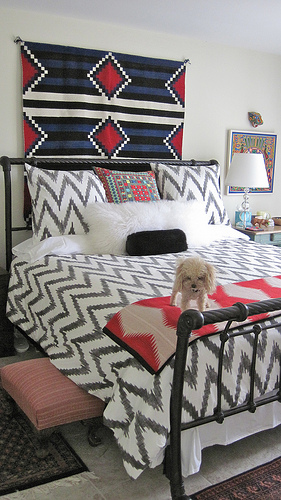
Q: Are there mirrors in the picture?
A: No, there are no mirrors.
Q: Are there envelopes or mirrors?
A: No, there are no mirrors or envelopes.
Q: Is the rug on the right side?
A: Yes, the rug is on the right of the image.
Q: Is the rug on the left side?
A: No, the rug is on the right of the image.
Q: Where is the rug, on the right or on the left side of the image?
A: The rug is on the right of the image.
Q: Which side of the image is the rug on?
A: The rug is on the right of the image.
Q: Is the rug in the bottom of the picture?
A: Yes, the rug is in the bottom of the image.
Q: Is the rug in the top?
A: No, the rug is in the bottom of the image.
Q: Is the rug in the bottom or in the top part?
A: The rug is in the bottom of the image.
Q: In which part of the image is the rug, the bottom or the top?
A: The rug is in the bottom of the image.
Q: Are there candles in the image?
A: No, there are no candles.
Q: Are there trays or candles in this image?
A: No, there are no candles or trays.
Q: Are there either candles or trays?
A: No, there are no candles or trays.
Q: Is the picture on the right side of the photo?
A: Yes, the picture is on the right of the image.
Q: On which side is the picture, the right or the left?
A: The picture is on the right of the image.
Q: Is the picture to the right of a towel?
A: No, the picture is to the right of a pillow.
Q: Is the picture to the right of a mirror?
A: No, the picture is to the right of the pillow.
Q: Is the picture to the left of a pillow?
A: No, the picture is to the right of a pillow.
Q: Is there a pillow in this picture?
A: Yes, there is a pillow.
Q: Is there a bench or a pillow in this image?
A: Yes, there is a pillow.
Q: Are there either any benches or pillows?
A: Yes, there is a pillow.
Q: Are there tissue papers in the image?
A: No, there are no tissue papers.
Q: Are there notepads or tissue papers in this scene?
A: No, there are no tissue papers or notepads.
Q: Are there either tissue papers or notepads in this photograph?
A: No, there are no tissue papers or notepads.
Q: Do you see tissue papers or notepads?
A: No, there are no tissue papers or notepads.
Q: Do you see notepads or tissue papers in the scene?
A: No, there are no tissue papers or notepads.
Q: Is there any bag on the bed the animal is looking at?
A: No, there is a pillow on the bed.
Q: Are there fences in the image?
A: No, there are no fences.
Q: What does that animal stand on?
A: The animal stands on the blanket.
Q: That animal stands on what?
A: The animal stands on the blanket.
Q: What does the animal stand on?
A: The animal stands on the blanket.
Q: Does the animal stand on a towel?
A: No, the animal stands on the blanket.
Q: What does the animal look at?
A: The animal looks at the bed.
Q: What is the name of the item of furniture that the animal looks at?
A: The piece of furniture is a bed.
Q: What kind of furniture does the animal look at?
A: The animal looks at the bed.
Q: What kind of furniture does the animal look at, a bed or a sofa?
A: The animal looks at a bed.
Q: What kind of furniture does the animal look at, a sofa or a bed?
A: The animal looks at a bed.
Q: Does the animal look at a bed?
A: Yes, the animal looks at a bed.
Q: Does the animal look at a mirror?
A: No, the animal looks at a bed.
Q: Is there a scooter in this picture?
A: No, there are no scooters.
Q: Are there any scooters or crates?
A: No, there are no scooters or crates.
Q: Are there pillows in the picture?
A: Yes, there is a pillow.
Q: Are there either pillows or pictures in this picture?
A: Yes, there is a pillow.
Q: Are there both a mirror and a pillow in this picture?
A: No, there is a pillow but no mirrors.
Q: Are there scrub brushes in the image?
A: No, there are no scrub brushes.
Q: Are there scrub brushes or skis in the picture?
A: No, there are no scrub brushes or skis.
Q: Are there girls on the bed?
A: No, there is a pillow on the bed.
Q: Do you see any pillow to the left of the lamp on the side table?
A: Yes, there is a pillow to the left of the lamp.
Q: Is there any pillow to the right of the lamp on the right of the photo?
A: No, the pillow is to the left of the lamp.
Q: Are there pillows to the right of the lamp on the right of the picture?
A: No, the pillow is to the left of the lamp.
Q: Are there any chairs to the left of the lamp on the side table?
A: No, there is a pillow to the left of the lamp.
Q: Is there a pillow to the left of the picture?
A: Yes, there is a pillow to the left of the picture.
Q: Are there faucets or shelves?
A: No, there are no faucets or shelves.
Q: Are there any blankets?
A: Yes, there is a blanket.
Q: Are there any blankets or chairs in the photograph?
A: Yes, there is a blanket.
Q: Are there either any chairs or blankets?
A: Yes, there is a blanket.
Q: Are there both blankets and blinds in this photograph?
A: No, there is a blanket but no blinds.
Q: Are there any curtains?
A: No, there are no curtains.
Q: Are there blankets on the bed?
A: Yes, there is a blanket on the bed.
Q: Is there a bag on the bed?
A: No, there is a blanket on the bed.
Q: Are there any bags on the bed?
A: No, there is a blanket on the bed.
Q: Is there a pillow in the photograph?
A: Yes, there is a pillow.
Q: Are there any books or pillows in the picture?
A: Yes, there is a pillow.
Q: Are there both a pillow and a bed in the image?
A: Yes, there are both a pillow and a bed.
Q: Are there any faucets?
A: No, there are no faucets.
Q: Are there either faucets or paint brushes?
A: No, there are no faucets or paint brushes.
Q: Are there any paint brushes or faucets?
A: No, there are no faucets or paint brushes.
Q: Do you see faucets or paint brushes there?
A: No, there are no faucets or paint brushes.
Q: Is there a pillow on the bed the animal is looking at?
A: Yes, there is a pillow on the bed.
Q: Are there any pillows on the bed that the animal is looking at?
A: Yes, there is a pillow on the bed.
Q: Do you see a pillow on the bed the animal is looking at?
A: Yes, there is a pillow on the bed.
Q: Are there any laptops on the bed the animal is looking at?
A: No, there is a pillow on the bed.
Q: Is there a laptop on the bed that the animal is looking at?
A: No, there is a pillow on the bed.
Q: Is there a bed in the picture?
A: Yes, there is a bed.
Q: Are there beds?
A: Yes, there is a bed.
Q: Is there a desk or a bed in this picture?
A: Yes, there is a bed.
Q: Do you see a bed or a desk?
A: Yes, there is a bed.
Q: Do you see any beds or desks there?
A: Yes, there is a bed.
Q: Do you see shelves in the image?
A: No, there are no shelves.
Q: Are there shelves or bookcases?
A: No, there are no shelves or bookcases.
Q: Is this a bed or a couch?
A: This is a bed.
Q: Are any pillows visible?
A: Yes, there is a pillow.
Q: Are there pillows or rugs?
A: Yes, there is a pillow.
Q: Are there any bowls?
A: No, there are no bowls.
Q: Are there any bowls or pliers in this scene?
A: No, there are no bowls or pliers.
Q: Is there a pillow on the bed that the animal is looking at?
A: Yes, there is a pillow on the bed.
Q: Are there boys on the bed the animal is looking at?
A: No, there is a pillow on the bed.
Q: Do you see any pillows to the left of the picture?
A: Yes, there is a pillow to the left of the picture.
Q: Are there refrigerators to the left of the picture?
A: No, there is a pillow to the left of the picture.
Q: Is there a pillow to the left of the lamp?
A: Yes, there is a pillow to the left of the lamp.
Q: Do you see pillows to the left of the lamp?
A: Yes, there is a pillow to the left of the lamp.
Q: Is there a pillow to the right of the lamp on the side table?
A: No, the pillow is to the left of the lamp.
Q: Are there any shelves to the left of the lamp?
A: No, there is a pillow to the left of the lamp.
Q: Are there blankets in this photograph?
A: Yes, there is a blanket.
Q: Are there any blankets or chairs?
A: Yes, there is a blanket.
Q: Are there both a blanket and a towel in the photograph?
A: No, there is a blanket but no towels.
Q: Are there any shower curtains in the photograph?
A: No, there are no shower curtains.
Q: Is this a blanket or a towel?
A: This is a blanket.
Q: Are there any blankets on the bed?
A: Yes, there is a blanket on the bed.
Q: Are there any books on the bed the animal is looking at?
A: No, there is a blanket on the bed.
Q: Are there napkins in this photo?
A: No, there are no napkins.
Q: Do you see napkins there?
A: No, there are no napkins.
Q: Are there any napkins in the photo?
A: No, there are no napkins.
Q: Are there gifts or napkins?
A: No, there are no napkins or gifts.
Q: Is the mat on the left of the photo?
A: Yes, the mat is on the left of the image.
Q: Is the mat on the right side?
A: No, the mat is on the left of the image.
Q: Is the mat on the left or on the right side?
A: The mat is on the left of the image.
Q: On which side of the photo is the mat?
A: The mat is on the left of the image.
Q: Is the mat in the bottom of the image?
A: Yes, the mat is in the bottom of the image.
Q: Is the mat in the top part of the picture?
A: No, the mat is in the bottom of the image.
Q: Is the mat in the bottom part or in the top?
A: The mat is in the bottom of the image.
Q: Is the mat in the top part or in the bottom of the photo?
A: The mat is in the bottom of the image.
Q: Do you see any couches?
A: No, there are no couches.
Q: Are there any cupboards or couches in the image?
A: No, there are no couches or cupboards.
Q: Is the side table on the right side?
A: Yes, the side table is on the right of the image.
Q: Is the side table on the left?
A: No, the side table is on the right of the image.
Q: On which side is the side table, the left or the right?
A: The side table is on the right of the image.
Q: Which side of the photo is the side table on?
A: The side table is on the right of the image.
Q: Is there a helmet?
A: Yes, there is a helmet.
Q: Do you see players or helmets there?
A: Yes, there is a helmet.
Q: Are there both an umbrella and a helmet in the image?
A: No, there is a helmet but no umbrellas.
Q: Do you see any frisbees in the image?
A: No, there are no frisbees.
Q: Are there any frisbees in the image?
A: No, there are no frisbees.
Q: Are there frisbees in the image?
A: No, there are no frisbees.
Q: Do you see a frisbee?
A: No, there are no frisbees.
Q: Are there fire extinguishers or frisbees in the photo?
A: No, there are no frisbees or fire extinguishers.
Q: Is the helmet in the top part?
A: Yes, the helmet is in the top of the image.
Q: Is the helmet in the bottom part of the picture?
A: No, the helmet is in the top of the image.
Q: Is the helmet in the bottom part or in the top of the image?
A: The helmet is in the top of the image.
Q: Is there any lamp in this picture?
A: Yes, there is a lamp.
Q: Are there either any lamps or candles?
A: Yes, there is a lamp.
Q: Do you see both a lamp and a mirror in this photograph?
A: No, there is a lamp but no mirrors.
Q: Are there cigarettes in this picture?
A: No, there are no cigarettes.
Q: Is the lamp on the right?
A: Yes, the lamp is on the right of the image.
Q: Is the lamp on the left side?
A: No, the lamp is on the right of the image.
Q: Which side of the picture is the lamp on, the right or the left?
A: The lamp is on the right of the image.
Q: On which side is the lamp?
A: The lamp is on the right of the image.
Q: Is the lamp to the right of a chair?
A: No, the lamp is to the right of a pillow.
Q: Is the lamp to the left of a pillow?
A: No, the lamp is to the right of a pillow.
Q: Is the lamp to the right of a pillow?
A: Yes, the lamp is to the right of a pillow.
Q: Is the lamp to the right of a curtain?
A: No, the lamp is to the right of a pillow.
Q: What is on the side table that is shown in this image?
A: The lamp is on the side table.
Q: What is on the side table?
A: The lamp is on the side table.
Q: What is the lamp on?
A: The lamp is on the side table.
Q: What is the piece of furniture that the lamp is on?
A: The piece of furniture is a side table.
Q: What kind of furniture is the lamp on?
A: The lamp is on the side table.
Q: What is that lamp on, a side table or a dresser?
A: The lamp is on a side table.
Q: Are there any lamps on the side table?
A: Yes, there is a lamp on the side table.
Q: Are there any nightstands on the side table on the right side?
A: No, there is a lamp on the side table.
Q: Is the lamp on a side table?
A: Yes, the lamp is on a side table.